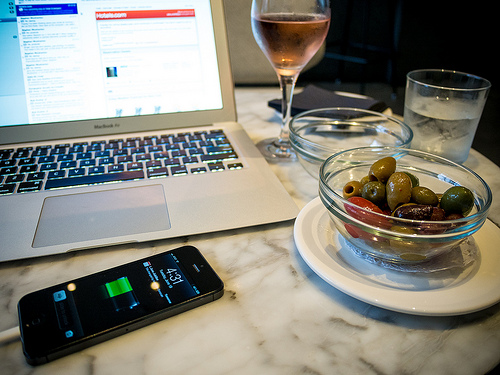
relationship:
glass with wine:
[251, 0, 332, 172] [251, 16, 334, 72]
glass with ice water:
[397, 62, 492, 165] [404, 101, 475, 158]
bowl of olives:
[318, 139, 492, 247] [366, 157, 440, 210]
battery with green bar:
[99, 272, 143, 315] [104, 276, 132, 299]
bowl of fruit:
[318, 139, 492, 247] [365, 160, 406, 195]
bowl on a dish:
[318, 139, 492, 247] [291, 188, 499, 317]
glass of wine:
[251, 0, 332, 172] [251, 16, 334, 72]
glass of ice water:
[397, 62, 492, 165] [404, 100, 478, 157]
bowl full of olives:
[318, 139, 492, 247] [366, 157, 440, 210]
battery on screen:
[99, 272, 143, 315] [43, 251, 201, 343]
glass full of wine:
[251, 0, 332, 172] [251, 16, 334, 72]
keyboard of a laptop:
[1, 119, 262, 196] [0, 1, 314, 265]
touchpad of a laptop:
[32, 179, 174, 251] [0, 1, 314, 265]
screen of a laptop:
[1, 0, 225, 130] [0, 1, 314, 265]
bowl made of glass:
[284, 102, 413, 156] [309, 112, 355, 126]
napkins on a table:
[265, 71, 385, 122] [15, 247, 457, 371]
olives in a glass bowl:
[366, 157, 440, 210] [318, 139, 492, 247]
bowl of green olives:
[318, 139, 492, 247] [366, 157, 440, 210]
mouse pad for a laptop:
[32, 179, 174, 251] [0, 1, 314, 265]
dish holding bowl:
[291, 188, 499, 317] [318, 139, 492, 247]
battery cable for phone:
[1, 324, 20, 351] [12, 242, 230, 366]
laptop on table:
[0, 1, 314, 265] [15, 247, 457, 371]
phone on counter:
[12, 242, 230, 366] [235, 236, 315, 374]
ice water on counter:
[404, 100, 478, 157] [235, 236, 315, 374]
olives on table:
[366, 157, 440, 210] [15, 247, 457, 371]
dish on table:
[291, 188, 499, 317] [15, 247, 457, 371]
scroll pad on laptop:
[32, 179, 174, 251] [0, 1, 314, 265]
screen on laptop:
[43, 251, 201, 343] [0, 1, 314, 265]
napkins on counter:
[265, 71, 385, 122] [235, 236, 315, 374]